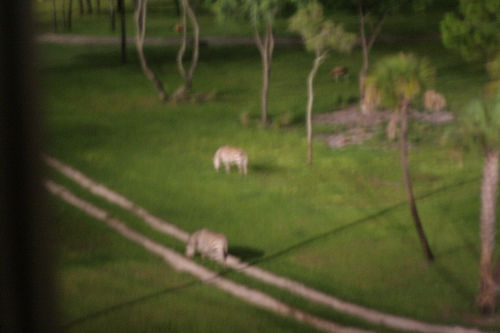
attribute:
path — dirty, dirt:
[36, 149, 426, 332]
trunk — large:
[258, 25, 272, 127]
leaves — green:
[211, 3, 498, 145]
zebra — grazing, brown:
[178, 140, 257, 268]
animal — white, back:
[207, 140, 255, 184]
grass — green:
[29, 52, 468, 326]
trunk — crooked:
[132, 1, 165, 98]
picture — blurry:
[7, 2, 495, 327]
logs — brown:
[253, 20, 277, 124]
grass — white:
[82, 175, 101, 194]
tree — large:
[472, 149, 500, 316]